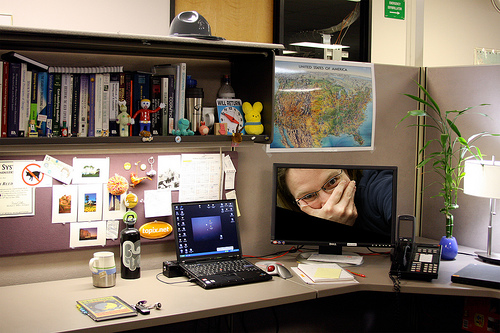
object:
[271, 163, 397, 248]
monitor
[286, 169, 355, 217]
man's face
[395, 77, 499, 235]
plant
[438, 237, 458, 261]
vase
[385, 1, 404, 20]
sign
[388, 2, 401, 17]
lettering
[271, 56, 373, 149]
map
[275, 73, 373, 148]
united states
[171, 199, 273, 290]
laptop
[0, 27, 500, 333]
desk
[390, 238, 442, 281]
phone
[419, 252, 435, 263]
note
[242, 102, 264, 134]
bunny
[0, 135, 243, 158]
shelf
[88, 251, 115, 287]
cup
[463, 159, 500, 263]
lamp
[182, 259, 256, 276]
keyboard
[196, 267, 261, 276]
edge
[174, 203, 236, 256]
screen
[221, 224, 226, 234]
part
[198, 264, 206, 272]
part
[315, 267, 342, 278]
paper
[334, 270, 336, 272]
part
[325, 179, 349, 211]
finger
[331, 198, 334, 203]
part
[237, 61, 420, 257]
wall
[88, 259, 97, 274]
handle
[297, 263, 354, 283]
notebook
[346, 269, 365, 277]
pen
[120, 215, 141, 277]
flask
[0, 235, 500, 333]
surface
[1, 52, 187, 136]
books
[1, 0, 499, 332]
office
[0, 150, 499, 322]
work space